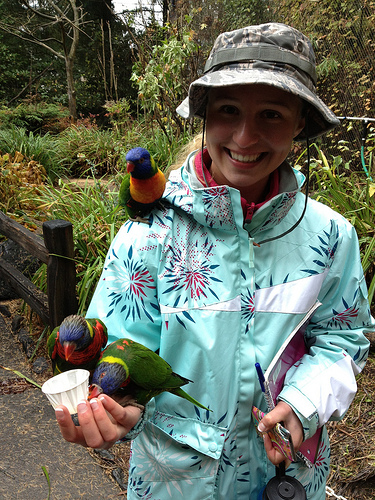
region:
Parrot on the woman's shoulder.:
[102, 125, 266, 260]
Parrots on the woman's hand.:
[41, 293, 155, 446]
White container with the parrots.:
[28, 359, 125, 438]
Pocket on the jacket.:
[141, 391, 244, 477]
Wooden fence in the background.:
[10, 186, 96, 323]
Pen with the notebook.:
[248, 346, 310, 466]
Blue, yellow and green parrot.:
[114, 139, 254, 256]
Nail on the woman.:
[244, 421, 283, 446]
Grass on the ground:
[40, 451, 58, 498]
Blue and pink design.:
[168, 238, 261, 318]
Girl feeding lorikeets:
[42, 21, 373, 498]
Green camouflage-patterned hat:
[174, 20, 341, 143]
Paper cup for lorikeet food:
[40, 367, 91, 414]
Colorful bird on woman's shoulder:
[117, 145, 166, 223]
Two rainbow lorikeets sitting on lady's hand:
[45, 313, 214, 419]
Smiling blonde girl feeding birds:
[40, 21, 373, 497]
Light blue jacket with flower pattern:
[84, 145, 373, 499]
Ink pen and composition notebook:
[254, 299, 325, 469]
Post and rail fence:
[0, 210, 78, 331]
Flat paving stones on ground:
[1, 311, 127, 497]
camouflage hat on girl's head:
[175, 22, 340, 139]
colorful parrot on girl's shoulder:
[119, 148, 164, 223]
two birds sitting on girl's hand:
[46, 315, 213, 410]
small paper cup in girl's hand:
[41, 368, 90, 413]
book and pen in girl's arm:
[254, 297, 326, 467]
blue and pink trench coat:
[87, 148, 368, 499]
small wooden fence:
[0, 209, 78, 332]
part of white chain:
[325, 486, 345, 499]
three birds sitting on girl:
[45, 145, 214, 411]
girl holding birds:
[42, 24, 373, 499]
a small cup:
[42, 377, 92, 400]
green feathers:
[123, 348, 165, 381]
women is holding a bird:
[257, 408, 295, 457]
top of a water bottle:
[272, 478, 308, 499]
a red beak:
[61, 344, 72, 358]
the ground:
[5, 416, 59, 498]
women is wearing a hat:
[204, 23, 315, 89]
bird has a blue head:
[96, 370, 121, 389]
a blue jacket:
[115, 215, 355, 336]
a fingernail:
[252, 416, 267, 433]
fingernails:
[72, 398, 105, 413]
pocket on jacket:
[149, 422, 219, 462]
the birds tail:
[175, 387, 218, 419]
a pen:
[252, 362, 265, 388]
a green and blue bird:
[102, 343, 157, 389]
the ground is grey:
[0, 430, 63, 488]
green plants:
[59, 196, 102, 214]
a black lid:
[265, 472, 303, 497]